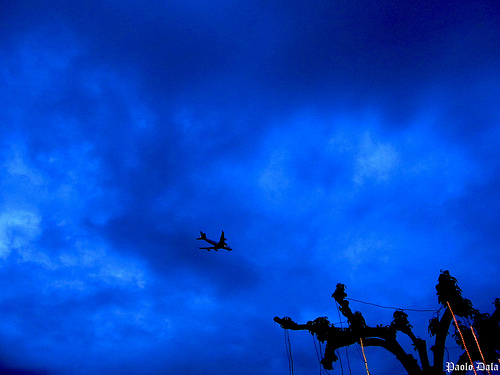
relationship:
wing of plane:
[214, 234, 233, 245] [193, 216, 243, 262]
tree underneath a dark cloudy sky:
[294, 279, 485, 363] [283, 100, 433, 170]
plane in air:
[196, 230, 234, 255] [15, 19, 478, 208]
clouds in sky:
[1, 201, 154, 310] [17, 22, 485, 148]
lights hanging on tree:
[442, 296, 479, 375] [257, 274, 485, 371]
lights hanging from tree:
[441, 296, 484, 364] [252, 261, 485, 369]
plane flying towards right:
[175, 210, 251, 263] [442, 9, 485, 356]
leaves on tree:
[426, 267, 479, 325] [253, 250, 483, 363]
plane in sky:
[196, 230, 234, 255] [2, 0, 497, 373]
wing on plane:
[216, 230, 227, 245] [194, 227, 234, 251]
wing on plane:
[199, 240, 215, 250] [196, 230, 234, 255]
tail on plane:
[197, 230, 207, 240] [193, 229, 231, 250]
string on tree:
[281, 322, 297, 372] [274, 268, 497, 371]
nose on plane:
[222, 242, 233, 251] [193, 229, 231, 250]